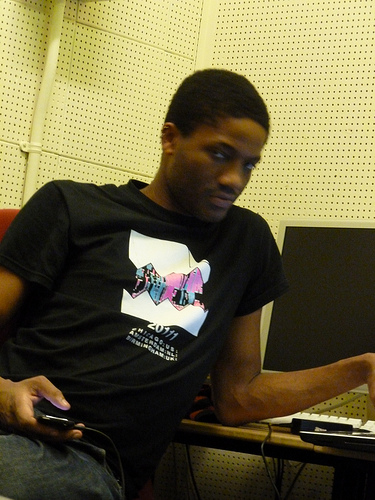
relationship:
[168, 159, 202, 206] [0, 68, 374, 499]
cheek of a guy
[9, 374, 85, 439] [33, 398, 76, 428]
hand holding cellphone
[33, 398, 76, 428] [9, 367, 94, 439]
cellphone in hand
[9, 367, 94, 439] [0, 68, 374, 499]
hand on guy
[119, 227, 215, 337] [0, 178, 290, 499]
design on shirt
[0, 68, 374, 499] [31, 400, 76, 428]
guy holding cellphone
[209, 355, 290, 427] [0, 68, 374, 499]
elbow on guy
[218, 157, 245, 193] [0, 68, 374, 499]
nose on guy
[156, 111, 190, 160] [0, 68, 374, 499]
ear on guy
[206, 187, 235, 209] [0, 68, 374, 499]
mouth on guy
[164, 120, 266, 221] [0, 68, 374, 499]
face on guy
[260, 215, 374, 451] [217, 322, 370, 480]
laptop on desk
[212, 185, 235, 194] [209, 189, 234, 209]
mustache on lip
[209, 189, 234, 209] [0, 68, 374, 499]
lip on guy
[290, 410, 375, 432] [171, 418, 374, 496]
keyboard on computer desk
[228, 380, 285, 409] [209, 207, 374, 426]
veins on arm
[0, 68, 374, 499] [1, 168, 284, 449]
guy wearing shirt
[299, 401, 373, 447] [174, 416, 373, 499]
stuff on desk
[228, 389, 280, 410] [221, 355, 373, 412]
veins on hand